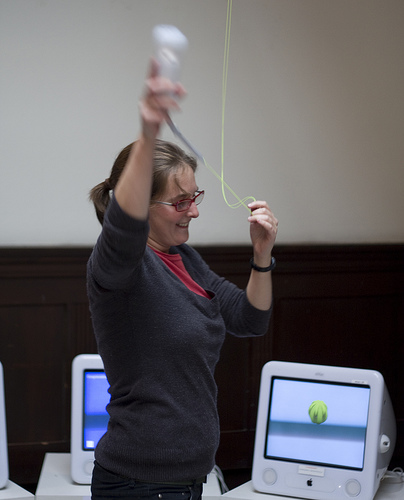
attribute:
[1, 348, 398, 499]
computer — on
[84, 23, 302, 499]
woman — smiling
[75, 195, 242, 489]
shirt — dark